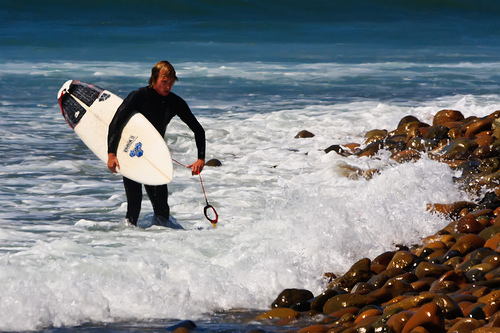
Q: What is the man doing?
A: Surfing.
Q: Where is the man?
A: Beach.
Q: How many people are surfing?
A: 1.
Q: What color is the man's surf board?
A: White black and blue.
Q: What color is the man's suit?
A: Black.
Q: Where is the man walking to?
A: Shore.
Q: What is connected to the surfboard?
A: Tether.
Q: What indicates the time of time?
A: Sunlight.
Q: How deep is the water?
A: Knee.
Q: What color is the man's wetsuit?
A: Black.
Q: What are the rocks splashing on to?
A: Rocks.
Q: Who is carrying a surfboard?
A: A man.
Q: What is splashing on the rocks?
A: Water.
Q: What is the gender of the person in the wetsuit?
A: Male.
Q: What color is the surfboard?
A: White.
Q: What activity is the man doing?
A: Surfing.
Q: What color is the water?
A: Blue.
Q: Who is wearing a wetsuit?
A: A surfer.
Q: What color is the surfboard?
A: White.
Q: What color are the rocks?
A: Brown.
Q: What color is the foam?
A: White.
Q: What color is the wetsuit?
A: Black.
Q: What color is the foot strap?
A: Black.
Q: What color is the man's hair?
A: Blonde.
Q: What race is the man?
A: White.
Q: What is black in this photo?
A: The wetsuit.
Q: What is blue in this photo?
A: The ocean.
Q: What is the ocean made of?
A: Water.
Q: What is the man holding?
A: Surfboard.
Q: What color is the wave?
A: White.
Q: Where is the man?
A: In the water.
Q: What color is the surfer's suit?
A: Black.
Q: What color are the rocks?
A: Brown.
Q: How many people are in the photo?
A: 1.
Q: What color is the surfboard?
A: White and black.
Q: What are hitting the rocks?
A: Waves.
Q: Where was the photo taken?
A: Ocean.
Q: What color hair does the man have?
A: Blonde.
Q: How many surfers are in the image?
A: One.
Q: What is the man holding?
A: A surfboard.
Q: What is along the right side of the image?
A: Rocks.